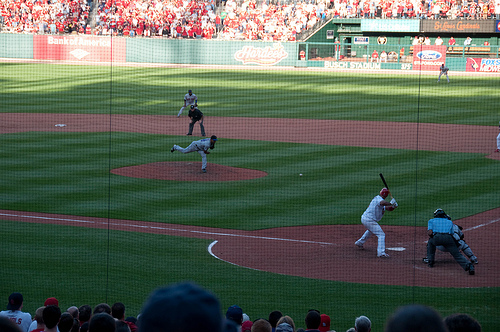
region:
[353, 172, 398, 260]
batter wearing red helmet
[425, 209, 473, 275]
umpire wears blue shirt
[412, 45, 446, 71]
advertisement on red background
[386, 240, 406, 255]
home plate is white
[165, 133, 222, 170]
pitcher is throwing ball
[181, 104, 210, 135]
umpire wears black shirt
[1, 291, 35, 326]
fan wearing blue cap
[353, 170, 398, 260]
player holding baseball bat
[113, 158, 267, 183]
pitcher's mound is brown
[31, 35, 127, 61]
advertisement is on wall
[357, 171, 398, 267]
batter up to bat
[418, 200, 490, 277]
baseball umpire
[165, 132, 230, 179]
pitcher just threw ball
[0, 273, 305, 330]
baseball player's audience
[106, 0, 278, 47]
crowd watching in infield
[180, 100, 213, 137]
referee watching game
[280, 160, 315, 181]
baseball flying through air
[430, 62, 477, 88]
base ball catcher in infield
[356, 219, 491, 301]
home plate first base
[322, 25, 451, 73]
base ball dug out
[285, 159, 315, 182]
small white ball in flight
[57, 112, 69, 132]
white mound on the field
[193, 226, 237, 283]
curved white edge at home plate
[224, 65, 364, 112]
large area of green artificial turf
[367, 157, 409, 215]
batter swinging black bat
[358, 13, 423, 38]
large green sign on stands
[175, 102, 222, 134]
umpire crouching in the field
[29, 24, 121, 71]
red sign with sponsor logo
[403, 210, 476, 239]
blue shirt on umpire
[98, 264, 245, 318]
blue cap on head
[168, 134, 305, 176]
pitcher throwing ball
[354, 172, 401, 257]
player is batting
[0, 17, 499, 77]
stands are green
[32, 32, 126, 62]
red sign on stand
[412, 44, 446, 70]
red and blue sign on stand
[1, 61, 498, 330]
green and red baseball field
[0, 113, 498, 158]
red dirt on field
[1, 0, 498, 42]
crowd with red shirts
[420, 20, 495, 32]
orange and black sign in stands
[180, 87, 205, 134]
men crouching in distance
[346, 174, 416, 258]
a baseball batter ready to hit the ball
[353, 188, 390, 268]
a baseball batter wearing white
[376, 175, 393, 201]
a baseball batter wearing red helmet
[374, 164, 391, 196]
baseball player has a black bat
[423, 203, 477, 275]
umpire is leaningin over catcher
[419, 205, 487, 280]
umpire wearing blue shirt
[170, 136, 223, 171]
pitcher released the ball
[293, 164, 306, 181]
baseball that was thrown through the air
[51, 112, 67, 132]
a white second base bag out in field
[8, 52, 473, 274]
a baseball game being played in a stadium